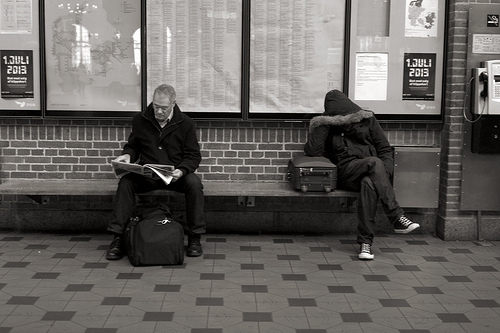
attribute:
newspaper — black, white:
[110, 160, 173, 184]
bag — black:
[121, 206, 185, 269]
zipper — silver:
[160, 217, 168, 226]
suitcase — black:
[285, 157, 334, 193]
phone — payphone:
[463, 59, 499, 122]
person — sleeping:
[304, 90, 419, 259]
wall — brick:
[2, 3, 497, 241]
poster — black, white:
[402, 51, 434, 102]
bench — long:
[2, 179, 363, 206]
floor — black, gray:
[0, 233, 497, 332]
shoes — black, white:
[358, 217, 420, 259]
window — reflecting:
[2, 1, 344, 111]